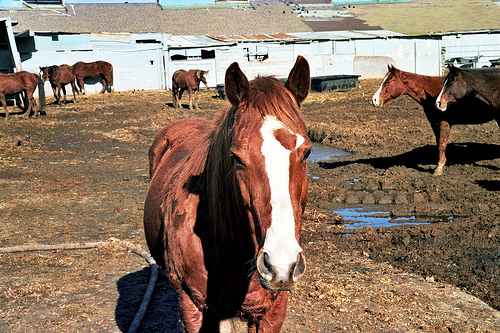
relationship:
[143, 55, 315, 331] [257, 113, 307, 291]
horse has some white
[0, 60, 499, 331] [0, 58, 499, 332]
horses are all standing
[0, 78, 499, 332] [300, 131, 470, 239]
ground that has some water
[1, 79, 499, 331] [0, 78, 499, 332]
mud on ground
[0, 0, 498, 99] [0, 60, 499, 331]
stables behind horses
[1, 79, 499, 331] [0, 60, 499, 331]
mud under horses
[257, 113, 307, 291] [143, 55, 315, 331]
white spot on horse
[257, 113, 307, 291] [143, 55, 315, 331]
white marking on horse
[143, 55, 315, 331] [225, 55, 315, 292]
horse has a head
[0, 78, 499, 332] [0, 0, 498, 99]
ground in front of stables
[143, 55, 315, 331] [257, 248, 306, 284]
horse has a nose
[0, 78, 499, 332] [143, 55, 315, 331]
ground under horse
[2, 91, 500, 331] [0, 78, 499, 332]
shade on ground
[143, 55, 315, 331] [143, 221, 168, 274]
horse has a stomach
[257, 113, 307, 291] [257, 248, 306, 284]
white above nose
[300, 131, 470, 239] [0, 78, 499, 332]
water on ground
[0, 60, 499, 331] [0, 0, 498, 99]
horses standing in front of stables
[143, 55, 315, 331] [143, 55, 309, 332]
horse standing alone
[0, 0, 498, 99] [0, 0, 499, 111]
stables in background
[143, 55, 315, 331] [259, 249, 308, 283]
horse has nostrils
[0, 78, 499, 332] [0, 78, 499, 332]
ground has dirt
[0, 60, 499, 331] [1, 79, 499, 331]
horses are standing on mud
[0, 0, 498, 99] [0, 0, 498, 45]
stables have a roof